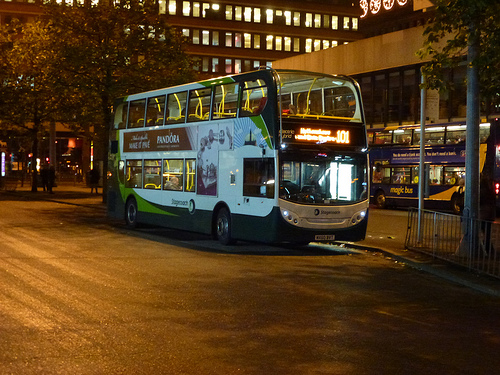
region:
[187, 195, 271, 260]
the wheel on a bus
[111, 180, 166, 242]
the back wheel on a bus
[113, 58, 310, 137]
the top of a bus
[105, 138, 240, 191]
the side window on a bus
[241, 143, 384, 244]
the windshield on a bus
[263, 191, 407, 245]
the headlight on a bus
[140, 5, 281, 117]
a building near a bus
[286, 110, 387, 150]
letters on a bus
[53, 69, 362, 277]
a bus on the street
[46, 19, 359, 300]
a bus on the road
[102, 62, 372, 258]
A double decker bus in the night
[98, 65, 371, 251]
A double decker bus in the night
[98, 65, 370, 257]
A double decker bus in the night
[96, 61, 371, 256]
A double decker bus in the night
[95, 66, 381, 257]
A double decker bus in the night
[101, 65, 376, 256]
A double decker bus in the night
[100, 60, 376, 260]
A double decker bus in the night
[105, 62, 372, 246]
a blue and green double-decked bus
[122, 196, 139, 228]
the wheel of a bus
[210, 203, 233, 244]
the wheel of a bus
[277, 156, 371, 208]
the windshield of a bus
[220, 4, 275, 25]
the windows of a building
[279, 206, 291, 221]
a light on the front of a bus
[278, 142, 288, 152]
a light on the front of a bus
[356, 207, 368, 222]
a light on the front of a bus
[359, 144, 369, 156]
a light on the front of a bus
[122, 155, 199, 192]
the windows on the side of a bus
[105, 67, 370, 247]
Double decker bus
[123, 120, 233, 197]
A Pandora sign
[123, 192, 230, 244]
The wheeles of the bus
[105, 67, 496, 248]
Two double decker buses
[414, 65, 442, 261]
A bus stop pole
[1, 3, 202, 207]
A tree behind the bus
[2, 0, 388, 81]
A building in the background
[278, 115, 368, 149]
A sign on the front of the bus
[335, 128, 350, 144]
The numbers 101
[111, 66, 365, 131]
The top deck of the bus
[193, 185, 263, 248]
the wheels on a bus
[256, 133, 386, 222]
the windshield on a bus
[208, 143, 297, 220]
the side window on a bus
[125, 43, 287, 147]
the top on a bus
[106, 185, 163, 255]
the back wheel on a bus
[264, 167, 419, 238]
the headlights on a bus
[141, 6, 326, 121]
a building near a bus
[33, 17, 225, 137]
a tree near a bus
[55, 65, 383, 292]
a bus on the streetr